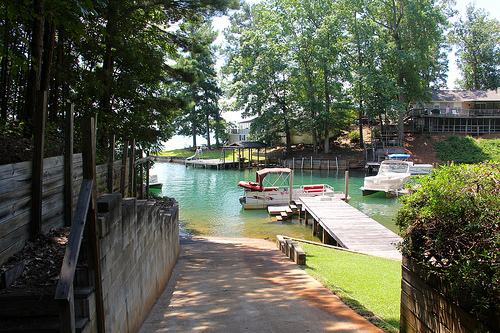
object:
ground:
[134, 196, 402, 332]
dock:
[296, 192, 410, 262]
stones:
[295, 249, 306, 266]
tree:
[441, 0, 499, 91]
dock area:
[293, 196, 434, 262]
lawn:
[280, 234, 402, 332]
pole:
[343, 171, 350, 200]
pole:
[61, 102, 77, 224]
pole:
[28, 91, 48, 239]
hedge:
[397, 250, 494, 331]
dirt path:
[133, 236, 391, 333]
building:
[370, 88, 499, 147]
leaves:
[453, 182, 467, 190]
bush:
[387, 156, 500, 332]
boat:
[234, 167, 350, 210]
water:
[147, 159, 405, 247]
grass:
[283, 237, 401, 332]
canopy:
[255, 166, 293, 191]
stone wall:
[79, 190, 181, 332]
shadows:
[137, 237, 399, 332]